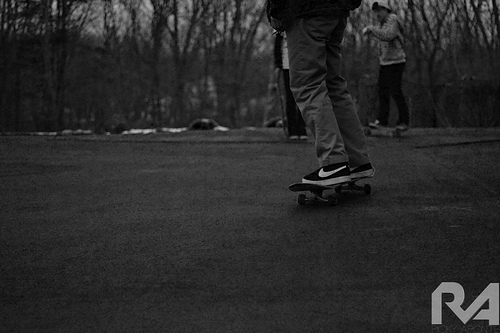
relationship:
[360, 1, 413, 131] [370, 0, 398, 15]
boy wearing cap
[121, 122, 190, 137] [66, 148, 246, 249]
snow covering ground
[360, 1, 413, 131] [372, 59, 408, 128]
boy wearing black pants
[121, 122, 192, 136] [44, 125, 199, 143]
snow covering ground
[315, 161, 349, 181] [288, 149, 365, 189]
check on sneakers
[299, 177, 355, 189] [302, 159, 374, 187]
bottom on sneakers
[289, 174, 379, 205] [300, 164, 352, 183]
skate board under foot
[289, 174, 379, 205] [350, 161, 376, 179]
skate board under foot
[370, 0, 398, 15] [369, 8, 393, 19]
cap on head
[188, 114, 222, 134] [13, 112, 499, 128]
car parked on road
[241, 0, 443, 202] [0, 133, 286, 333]
men on ground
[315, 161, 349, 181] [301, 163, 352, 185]
check on shoes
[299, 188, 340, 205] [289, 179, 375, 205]
wheels on skateboard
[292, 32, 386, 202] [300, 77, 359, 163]
pants covering legs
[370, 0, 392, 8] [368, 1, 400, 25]
cap on head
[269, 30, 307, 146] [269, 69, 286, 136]
person holding skateboard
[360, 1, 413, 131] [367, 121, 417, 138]
boy holding skateboard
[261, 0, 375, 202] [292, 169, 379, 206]
men holding skateboard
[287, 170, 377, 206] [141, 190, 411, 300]
skate board on ground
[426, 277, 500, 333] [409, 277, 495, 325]
corner in corner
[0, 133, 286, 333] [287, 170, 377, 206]
ground under skate board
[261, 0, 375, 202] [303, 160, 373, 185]
men wearing shoes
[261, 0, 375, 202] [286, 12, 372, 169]
men wearing pants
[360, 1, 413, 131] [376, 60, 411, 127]
boy wearing pants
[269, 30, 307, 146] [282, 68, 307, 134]
person wearing pants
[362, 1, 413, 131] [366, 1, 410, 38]
boy wearing hat